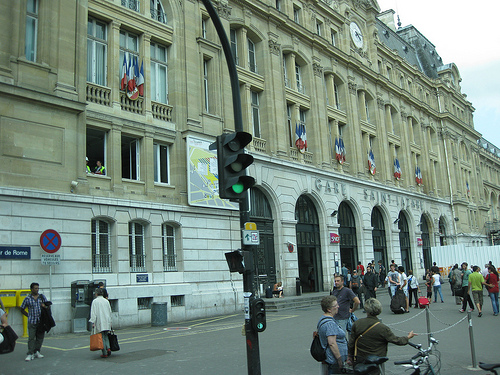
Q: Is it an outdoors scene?
A: Yes, it is outdoors.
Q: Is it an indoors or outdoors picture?
A: It is outdoors.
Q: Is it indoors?
A: No, it is outdoors.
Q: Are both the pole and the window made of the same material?
A: Yes, both the pole and the window are made of metal.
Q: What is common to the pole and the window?
A: The material, both the pole and the window are metallic.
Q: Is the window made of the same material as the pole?
A: Yes, both the window and the pole are made of metal.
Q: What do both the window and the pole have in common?
A: The material, both the window and the pole are metallic.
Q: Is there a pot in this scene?
A: No, there are no pots.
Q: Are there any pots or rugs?
A: No, there are no pots or rugs.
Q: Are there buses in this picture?
A: No, there are no buses.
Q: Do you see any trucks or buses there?
A: No, there are no buses or trucks.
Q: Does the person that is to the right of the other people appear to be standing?
A: Yes, the person is standing.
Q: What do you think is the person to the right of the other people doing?
A: The person is standing.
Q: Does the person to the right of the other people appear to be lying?
A: No, the person is standing.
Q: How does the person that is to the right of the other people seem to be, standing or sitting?
A: The person is standing.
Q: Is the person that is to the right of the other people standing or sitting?
A: The person is standing.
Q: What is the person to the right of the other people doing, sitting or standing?
A: The person is standing.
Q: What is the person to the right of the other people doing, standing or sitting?
A: The person is standing.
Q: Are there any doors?
A: Yes, there is a door.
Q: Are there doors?
A: Yes, there is a door.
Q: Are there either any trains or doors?
A: Yes, there is a door.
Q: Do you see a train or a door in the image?
A: Yes, there is a door.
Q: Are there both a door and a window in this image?
A: Yes, there are both a door and a window.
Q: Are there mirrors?
A: No, there are no mirrors.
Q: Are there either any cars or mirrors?
A: No, there are no mirrors or cars.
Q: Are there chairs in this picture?
A: No, there are no chairs.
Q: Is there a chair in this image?
A: No, there are no chairs.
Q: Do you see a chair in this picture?
A: No, there are no chairs.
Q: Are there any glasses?
A: No, there are no glasses.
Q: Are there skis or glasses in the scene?
A: No, there are no glasses or skis.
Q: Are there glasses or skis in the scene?
A: No, there are no glasses or skis.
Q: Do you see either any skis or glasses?
A: No, there are no glasses or skis.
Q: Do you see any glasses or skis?
A: No, there are no glasses or skis.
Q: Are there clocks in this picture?
A: Yes, there is a clock.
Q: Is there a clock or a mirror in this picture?
A: Yes, there is a clock.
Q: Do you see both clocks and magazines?
A: No, there is a clock but no magazines.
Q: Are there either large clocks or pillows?
A: Yes, there is a large clock.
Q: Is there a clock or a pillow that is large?
A: Yes, the clock is large.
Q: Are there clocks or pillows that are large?
A: Yes, the clock is large.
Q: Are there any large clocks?
A: Yes, there is a large clock.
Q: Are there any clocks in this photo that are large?
A: Yes, there is a clock that is large.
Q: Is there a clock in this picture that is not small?
A: Yes, there is a large clock.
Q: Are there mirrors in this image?
A: No, there are no mirrors.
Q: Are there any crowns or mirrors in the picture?
A: No, there are no mirrors or crowns.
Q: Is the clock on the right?
A: Yes, the clock is on the right of the image.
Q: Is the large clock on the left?
A: No, the clock is on the right of the image.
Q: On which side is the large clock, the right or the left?
A: The clock is on the right of the image.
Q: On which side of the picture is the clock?
A: The clock is on the right of the image.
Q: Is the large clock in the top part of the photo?
A: Yes, the clock is in the top of the image.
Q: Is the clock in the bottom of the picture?
A: No, the clock is in the top of the image.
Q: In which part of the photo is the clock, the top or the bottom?
A: The clock is in the top of the image.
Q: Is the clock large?
A: Yes, the clock is large.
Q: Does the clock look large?
A: Yes, the clock is large.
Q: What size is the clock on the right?
A: The clock is large.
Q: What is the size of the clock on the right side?
A: The clock is large.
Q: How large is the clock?
A: The clock is large.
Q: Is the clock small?
A: No, the clock is large.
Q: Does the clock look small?
A: No, the clock is large.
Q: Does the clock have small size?
A: No, the clock is large.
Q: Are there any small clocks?
A: No, there is a clock but it is large.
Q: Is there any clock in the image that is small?
A: No, there is a clock but it is large.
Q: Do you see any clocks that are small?
A: No, there is a clock but it is large.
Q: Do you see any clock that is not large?
A: No, there is a clock but it is large.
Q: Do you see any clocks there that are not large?
A: No, there is a clock but it is large.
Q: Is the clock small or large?
A: The clock is large.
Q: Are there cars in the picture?
A: No, there are no cars.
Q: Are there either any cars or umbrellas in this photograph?
A: No, there are no cars or umbrellas.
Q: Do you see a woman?
A: Yes, there is a woman.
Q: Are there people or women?
A: Yes, there is a woman.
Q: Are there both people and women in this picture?
A: Yes, there are both a woman and a person.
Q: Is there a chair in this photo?
A: No, there are no chairs.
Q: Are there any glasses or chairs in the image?
A: No, there are no chairs or glasses.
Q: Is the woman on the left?
A: Yes, the woman is on the left of the image.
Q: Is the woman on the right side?
A: No, the woman is on the left of the image.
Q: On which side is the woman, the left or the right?
A: The woman is on the left of the image.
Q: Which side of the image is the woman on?
A: The woman is on the left of the image.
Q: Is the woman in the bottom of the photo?
A: Yes, the woman is in the bottom of the image.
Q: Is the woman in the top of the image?
A: No, the woman is in the bottom of the image.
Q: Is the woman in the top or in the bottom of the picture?
A: The woman is in the bottom of the image.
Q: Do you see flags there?
A: Yes, there is a flag.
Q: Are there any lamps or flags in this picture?
A: Yes, there is a flag.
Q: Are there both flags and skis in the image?
A: No, there is a flag but no skis.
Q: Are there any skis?
A: No, there are no skis.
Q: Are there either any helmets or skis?
A: No, there are no skis or helmets.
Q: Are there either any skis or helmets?
A: No, there are no skis or helmets.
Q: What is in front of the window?
A: The flag is in front of the window.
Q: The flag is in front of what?
A: The flag is in front of the window.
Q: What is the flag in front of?
A: The flag is in front of the window.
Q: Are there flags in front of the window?
A: Yes, there is a flag in front of the window.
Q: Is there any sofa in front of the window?
A: No, there is a flag in front of the window.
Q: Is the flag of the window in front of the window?
A: Yes, the flag is in front of the window.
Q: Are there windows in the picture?
A: Yes, there is a window.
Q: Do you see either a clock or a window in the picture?
A: Yes, there is a window.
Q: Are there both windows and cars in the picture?
A: No, there is a window but no cars.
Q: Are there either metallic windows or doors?
A: Yes, there is a metal window.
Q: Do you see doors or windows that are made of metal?
A: Yes, the window is made of metal.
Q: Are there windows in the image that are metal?
A: Yes, there is a metal window.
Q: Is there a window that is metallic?
A: Yes, there is a window that is metallic.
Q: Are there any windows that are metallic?
A: Yes, there is a window that is metallic.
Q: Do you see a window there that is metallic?
A: Yes, there is a window that is metallic.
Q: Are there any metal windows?
A: Yes, there is a window that is made of metal.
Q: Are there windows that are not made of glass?
A: Yes, there is a window that is made of metal.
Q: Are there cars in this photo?
A: No, there are no cars.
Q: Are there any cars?
A: No, there are no cars.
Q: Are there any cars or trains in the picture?
A: No, there are no cars or trains.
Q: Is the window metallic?
A: Yes, the window is metallic.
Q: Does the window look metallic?
A: Yes, the window is metallic.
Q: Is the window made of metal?
A: Yes, the window is made of metal.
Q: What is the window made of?
A: The window is made of metal.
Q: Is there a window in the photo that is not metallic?
A: No, there is a window but it is metallic.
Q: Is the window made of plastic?
A: No, the window is made of metal.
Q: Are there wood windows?
A: No, there is a window but it is made of metal.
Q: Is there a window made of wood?
A: No, there is a window but it is made of metal.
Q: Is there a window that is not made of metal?
A: No, there is a window but it is made of metal.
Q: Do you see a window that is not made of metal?
A: No, there is a window but it is made of metal.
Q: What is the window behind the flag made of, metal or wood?
A: The window is made of metal.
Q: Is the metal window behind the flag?
A: Yes, the window is behind the flag.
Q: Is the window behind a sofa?
A: No, the window is behind the flag.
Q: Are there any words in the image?
A: Yes, there are words.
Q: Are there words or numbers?
A: Yes, there are words.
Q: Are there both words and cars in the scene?
A: No, there are words but no cars.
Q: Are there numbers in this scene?
A: No, there are no numbers.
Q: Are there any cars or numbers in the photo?
A: No, there are no numbers or cars.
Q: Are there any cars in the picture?
A: No, there are no cars.